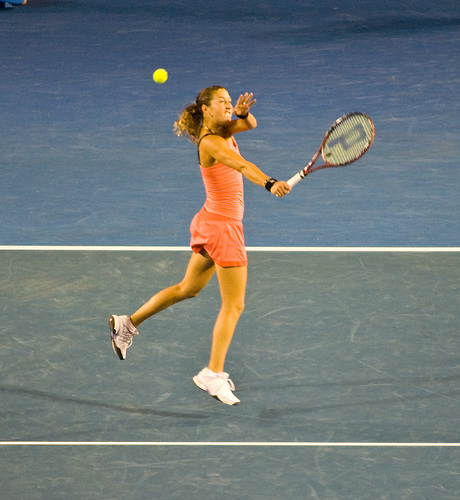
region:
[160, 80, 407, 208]
a woman holding a tennis racket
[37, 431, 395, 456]
white lines on a tennis court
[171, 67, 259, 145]
a woman with a pony tail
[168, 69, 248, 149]
a woman with brown hair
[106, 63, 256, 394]
a woman with both feet off the ground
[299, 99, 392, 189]
a tennis racket with a letter P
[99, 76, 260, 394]
a woman wearing white tennis shoes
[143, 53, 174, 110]
a tennis ball in the air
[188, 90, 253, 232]
a woman wearing a tank top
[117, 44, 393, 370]
a woman playing tennis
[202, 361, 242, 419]
woman wearing white tennis shoes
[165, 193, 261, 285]
woman wearng pink shorts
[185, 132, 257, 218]
woman wearing pink a tshirt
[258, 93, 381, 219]
woman wearing a tennis racket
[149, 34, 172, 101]
yellow tennis racket on a court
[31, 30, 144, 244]
tennis court with a woman jumping on it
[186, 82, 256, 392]
woman hitting a ball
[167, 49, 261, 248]
woman wearing her hair in a pony tail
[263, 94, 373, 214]
maroon tennis racket in a woman hand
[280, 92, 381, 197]
a moroon tennis racket with the letter on it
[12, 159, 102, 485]
tennis court with white stripes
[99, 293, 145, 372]
white tennis shoe with black sole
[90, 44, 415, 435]
white female tennis player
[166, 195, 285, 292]
peach colored athletic shorts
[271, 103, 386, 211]
red and white tennis racket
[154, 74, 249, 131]
caucasian woman with curly blonde hair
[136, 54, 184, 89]
tennis ball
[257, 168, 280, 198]
black wrist band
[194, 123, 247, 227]
peach colored athletic shirt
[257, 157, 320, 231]
right hand holding tennis racket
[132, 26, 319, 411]
girl playing tennis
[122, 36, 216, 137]
green tennis ball in the air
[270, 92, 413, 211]
blue P on tennis racket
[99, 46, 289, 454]
girl is off the ground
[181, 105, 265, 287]
girl in pink outfit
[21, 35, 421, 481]
blue and green tennis court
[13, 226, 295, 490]
white lines on tennis court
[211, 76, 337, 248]
girl wearing black wrist bands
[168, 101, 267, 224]
girl wearing pink tank top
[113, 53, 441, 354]
a girl is swinging a racket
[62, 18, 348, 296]
a girl is swinging a racket